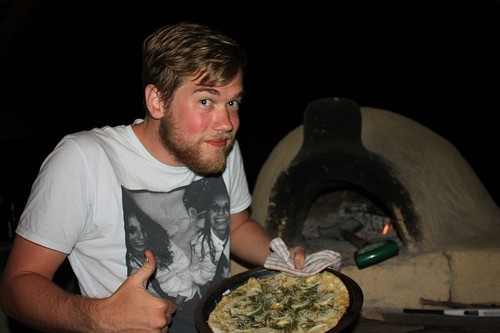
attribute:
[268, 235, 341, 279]
rag — white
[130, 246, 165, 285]
thumb — up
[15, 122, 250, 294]
shirt — white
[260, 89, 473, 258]
oven — stone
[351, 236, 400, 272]
handle — green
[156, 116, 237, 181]
beard — brown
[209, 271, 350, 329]
pizza — cooked, baked, small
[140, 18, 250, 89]
hair — blond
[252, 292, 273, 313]
toppings — green, white